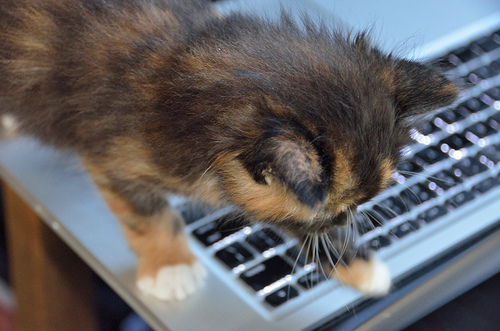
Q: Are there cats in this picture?
A: Yes, there is a cat.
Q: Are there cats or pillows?
A: Yes, there is a cat.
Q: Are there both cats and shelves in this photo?
A: No, there is a cat but no shelves.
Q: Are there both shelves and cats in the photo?
A: No, there is a cat but no shelves.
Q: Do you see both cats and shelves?
A: No, there is a cat but no shelves.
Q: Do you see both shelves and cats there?
A: No, there is a cat but no shelves.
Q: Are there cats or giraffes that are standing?
A: Yes, the cat is standing.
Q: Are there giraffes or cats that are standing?
A: Yes, the cat is standing.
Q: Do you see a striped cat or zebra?
A: Yes, there is a striped cat.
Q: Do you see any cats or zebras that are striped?
A: Yes, the cat is striped.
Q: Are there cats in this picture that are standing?
A: Yes, there is a cat that is standing.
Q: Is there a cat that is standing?
A: Yes, there is a cat that is standing.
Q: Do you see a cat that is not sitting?
A: Yes, there is a cat that is standing .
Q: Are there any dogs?
A: No, there are no dogs.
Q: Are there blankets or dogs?
A: No, there are no dogs or blankets.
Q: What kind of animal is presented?
A: The animal is a cat.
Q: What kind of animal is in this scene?
A: The animal is a cat.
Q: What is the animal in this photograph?
A: The animal is a cat.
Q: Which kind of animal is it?
A: The animal is a cat.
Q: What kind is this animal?
A: This is a cat.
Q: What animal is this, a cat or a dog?
A: This is a cat.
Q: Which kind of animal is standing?
A: The animal is a cat.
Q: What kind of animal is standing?
A: The animal is a cat.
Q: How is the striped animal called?
A: The animal is a cat.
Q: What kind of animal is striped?
A: The animal is a cat.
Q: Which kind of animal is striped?
A: The animal is a cat.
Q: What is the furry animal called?
A: The animal is a cat.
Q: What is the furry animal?
A: The animal is a cat.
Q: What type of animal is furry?
A: The animal is a cat.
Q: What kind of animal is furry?
A: The animal is a cat.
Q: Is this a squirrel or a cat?
A: This is a cat.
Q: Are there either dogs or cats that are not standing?
A: No, there is a cat but it is standing.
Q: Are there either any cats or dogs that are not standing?
A: No, there is a cat but it is standing.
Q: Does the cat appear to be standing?
A: Yes, the cat is standing.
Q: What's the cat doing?
A: The cat is standing.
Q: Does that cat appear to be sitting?
A: No, the cat is standing.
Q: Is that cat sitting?
A: No, the cat is standing.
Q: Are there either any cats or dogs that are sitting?
A: No, there is a cat but it is standing.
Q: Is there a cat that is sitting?
A: No, there is a cat but it is standing.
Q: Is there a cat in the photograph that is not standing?
A: No, there is a cat but it is standing.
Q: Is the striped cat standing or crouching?
A: The cat is standing.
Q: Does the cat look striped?
A: Yes, the cat is striped.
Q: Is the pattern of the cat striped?
A: Yes, the cat is striped.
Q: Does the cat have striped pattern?
A: Yes, the cat is striped.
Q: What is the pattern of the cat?
A: The cat is striped.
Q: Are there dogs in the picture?
A: No, there are no dogs.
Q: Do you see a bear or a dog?
A: No, there are no dogs or bears.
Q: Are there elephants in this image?
A: No, there are no elephants.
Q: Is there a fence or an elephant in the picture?
A: No, there are no elephants or fences.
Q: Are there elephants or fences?
A: No, there are no elephants or fences.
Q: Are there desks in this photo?
A: Yes, there is a desk.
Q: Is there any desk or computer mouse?
A: Yes, there is a desk.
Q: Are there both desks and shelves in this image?
A: No, there is a desk but no shelves.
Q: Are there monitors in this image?
A: No, there are no monitors.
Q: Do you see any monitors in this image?
A: No, there are no monitors.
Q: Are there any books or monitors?
A: No, there are no monitors or books.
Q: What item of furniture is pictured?
A: The piece of furniture is a desk.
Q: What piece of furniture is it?
A: The piece of furniture is a desk.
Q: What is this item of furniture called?
A: This is a desk.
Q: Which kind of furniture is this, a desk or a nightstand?
A: This is a desk.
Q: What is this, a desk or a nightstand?
A: This is a desk.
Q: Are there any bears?
A: No, there are no bears.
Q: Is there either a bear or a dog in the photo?
A: No, there are no bears or dogs.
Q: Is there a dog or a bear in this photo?
A: No, there are no bears or dogs.